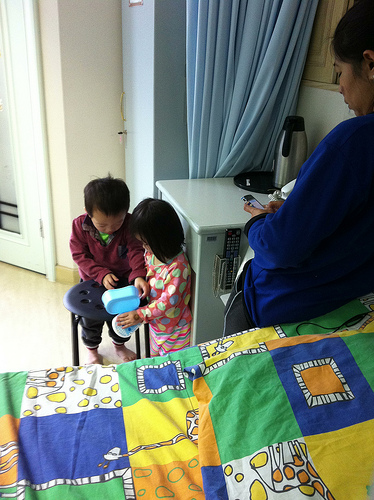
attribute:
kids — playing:
[57, 185, 177, 299]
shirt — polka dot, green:
[127, 253, 226, 348]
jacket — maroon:
[71, 200, 154, 270]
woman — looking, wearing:
[276, 28, 359, 299]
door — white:
[11, 45, 37, 270]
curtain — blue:
[179, 26, 286, 129]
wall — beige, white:
[55, 43, 113, 112]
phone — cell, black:
[228, 177, 301, 267]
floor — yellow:
[13, 274, 96, 370]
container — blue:
[84, 271, 172, 318]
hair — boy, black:
[72, 166, 117, 209]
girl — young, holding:
[122, 194, 213, 402]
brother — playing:
[69, 176, 131, 272]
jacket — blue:
[262, 139, 371, 313]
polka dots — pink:
[149, 260, 215, 329]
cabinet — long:
[182, 181, 292, 297]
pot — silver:
[270, 90, 328, 186]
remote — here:
[222, 180, 273, 217]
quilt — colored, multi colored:
[69, 356, 328, 472]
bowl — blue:
[83, 251, 199, 353]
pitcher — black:
[229, 85, 341, 209]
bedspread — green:
[193, 348, 347, 498]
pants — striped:
[76, 296, 119, 370]